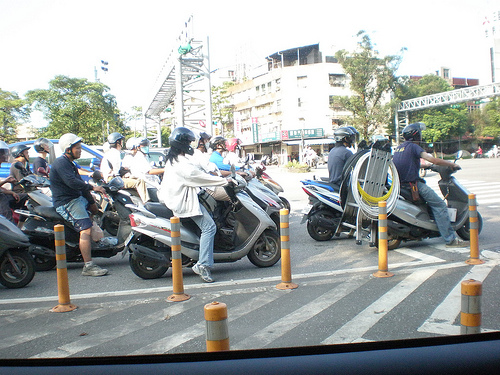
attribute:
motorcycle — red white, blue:
[134, 174, 295, 280]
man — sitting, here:
[395, 120, 456, 242]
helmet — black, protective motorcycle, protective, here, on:
[396, 121, 438, 141]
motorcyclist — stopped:
[312, 113, 371, 238]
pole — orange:
[164, 206, 187, 301]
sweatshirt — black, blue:
[41, 160, 96, 196]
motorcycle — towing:
[361, 173, 482, 230]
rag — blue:
[178, 36, 202, 60]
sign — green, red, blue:
[277, 114, 343, 154]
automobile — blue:
[2, 124, 117, 189]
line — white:
[272, 282, 359, 330]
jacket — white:
[164, 161, 226, 234]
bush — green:
[418, 108, 448, 142]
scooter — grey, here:
[33, 193, 156, 267]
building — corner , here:
[224, 69, 384, 169]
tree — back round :
[33, 79, 129, 146]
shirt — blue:
[392, 153, 419, 170]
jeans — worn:
[412, 188, 466, 246]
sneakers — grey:
[185, 261, 215, 282]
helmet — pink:
[225, 135, 249, 157]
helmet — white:
[52, 131, 84, 149]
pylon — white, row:
[274, 207, 301, 288]